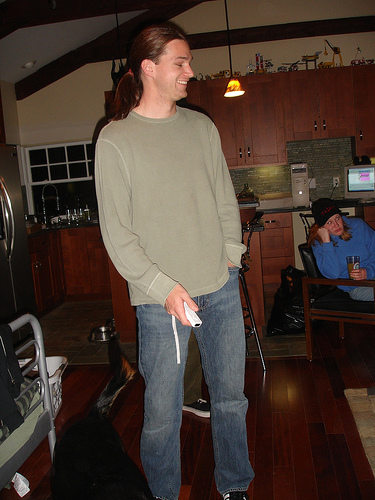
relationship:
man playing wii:
[93, 20, 256, 499] [179, 300, 204, 330]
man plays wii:
[93, 20, 256, 499] [179, 300, 204, 330]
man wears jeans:
[93, 20, 256, 499] [136, 266, 257, 498]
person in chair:
[316, 197, 373, 303] [302, 244, 375, 365]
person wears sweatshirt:
[316, 197, 373, 303] [314, 216, 374, 287]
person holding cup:
[316, 197, 373, 303] [346, 254, 362, 275]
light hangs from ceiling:
[222, 79, 247, 100] [2, 1, 375, 105]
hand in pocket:
[163, 286, 196, 329] [224, 263, 243, 294]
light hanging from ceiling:
[222, 79, 247, 100] [2, 1, 375, 105]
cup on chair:
[346, 254, 362, 275] [302, 244, 375, 365]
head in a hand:
[313, 200, 346, 241] [317, 228, 332, 242]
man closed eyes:
[93, 20, 256, 499] [174, 59, 193, 70]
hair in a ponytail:
[91, 22, 188, 149] [91, 60, 138, 145]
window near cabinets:
[18, 143, 96, 218] [197, 69, 374, 162]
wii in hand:
[179, 300, 204, 330] [163, 286, 196, 329]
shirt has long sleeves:
[93, 107, 249, 309] [91, 142, 175, 308]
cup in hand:
[346, 254, 362, 275] [349, 269, 365, 283]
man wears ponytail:
[93, 20, 256, 499] [91, 60, 138, 145]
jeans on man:
[136, 266, 257, 498] [93, 20, 256, 499]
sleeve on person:
[313, 241, 345, 280] [316, 197, 373, 303]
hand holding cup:
[349, 269, 365, 283] [346, 254, 362, 275]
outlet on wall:
[332, 176, 344, 188] [223, 139, 373, 207]